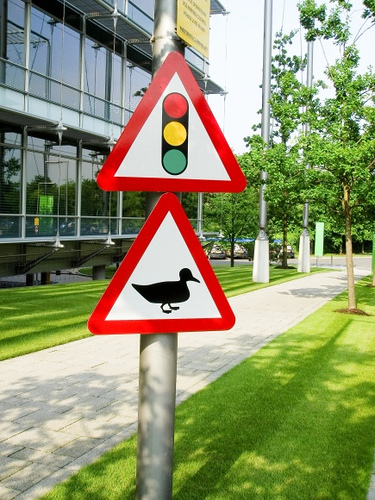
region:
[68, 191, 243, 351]
Triangle duck warning sign.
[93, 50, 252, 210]
Traffic light warning sign.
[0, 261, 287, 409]
Grey brick formed sidewalk.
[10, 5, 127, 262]
Building with large metal framed windows.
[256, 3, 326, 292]
Cement anchored metal poles.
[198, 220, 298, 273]
Vehicles parked in parking lot.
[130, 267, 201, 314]
A black duck.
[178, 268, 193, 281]
Head of a black duck.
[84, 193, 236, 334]
A red triangle sign with a black duck in it.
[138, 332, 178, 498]
A grey pole under triangle signs.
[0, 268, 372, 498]
A long block concrete walkway.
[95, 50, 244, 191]
A red and white triangle sign with red, green and yellow lights.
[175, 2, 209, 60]
Yellow sign with black writing.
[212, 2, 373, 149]
A white sky.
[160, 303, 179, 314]
Black feet and legs of a duck.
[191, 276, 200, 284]
Black bird beak.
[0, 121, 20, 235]
window on the elevated building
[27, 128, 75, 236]
window on the elevated building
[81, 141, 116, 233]
window on the elevated building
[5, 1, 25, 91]
window on the elevated building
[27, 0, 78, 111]
window on the elevated building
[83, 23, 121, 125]
window on the elevated building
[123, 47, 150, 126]
window on the elevated building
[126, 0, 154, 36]
window on the elevated building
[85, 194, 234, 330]
duck crossing next to the elevated building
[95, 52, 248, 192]
traffic sign by the elevated building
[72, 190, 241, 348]
sign for duck crossing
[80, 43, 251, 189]
sign for a traffic light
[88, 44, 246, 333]
two signs on a pole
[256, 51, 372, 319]
trees in front of building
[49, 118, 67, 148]
lights on a building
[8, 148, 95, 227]
blinds in a building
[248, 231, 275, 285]
concrete base for a pole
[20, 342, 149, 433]
pathway between grass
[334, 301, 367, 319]
mulch around the tree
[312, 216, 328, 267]
electric box in the lot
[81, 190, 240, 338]
a triangle on a post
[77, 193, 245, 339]
a triangle has red border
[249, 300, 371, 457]
shadow over the green grass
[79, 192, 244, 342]
a black duck on a sign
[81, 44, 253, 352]
two triangles on a pole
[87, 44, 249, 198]
a triangle on a pole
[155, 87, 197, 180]
a traffic light on a pole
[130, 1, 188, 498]
a silver pole on grass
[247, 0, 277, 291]
a pole is color silver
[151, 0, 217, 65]
a yellow color on pole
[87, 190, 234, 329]
A sign identifying ducks in the area.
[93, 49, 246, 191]
A sign warning of a traffic light ahead.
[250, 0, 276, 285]
A light pole along the path.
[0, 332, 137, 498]
A brick path.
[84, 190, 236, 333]
triangle sign with black duck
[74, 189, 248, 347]
red and white duck sign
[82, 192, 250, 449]
red and white duck sign on pole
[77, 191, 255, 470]
red and white duck sign by sidewalk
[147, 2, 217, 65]
yellow sign on grey pole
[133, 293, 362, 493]
shadow of sign on ground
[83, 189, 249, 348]
red and white duck crossing sign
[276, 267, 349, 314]
shadow of tree on sidewalk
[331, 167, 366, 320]
brown mulch under green tree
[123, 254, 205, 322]
black duck on white sign